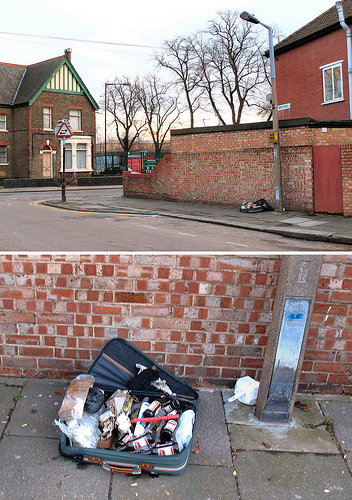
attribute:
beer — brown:
[136, 398, 193, 449]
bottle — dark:
[142, 387, 182, 422]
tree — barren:
[109, 61, 195, 161]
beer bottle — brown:
[145, 392, 171, 414]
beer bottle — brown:
[162, 412, 178, 439]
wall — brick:
[122, 117, 351, 216]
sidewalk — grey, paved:
[101, 158, 349, 271]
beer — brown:
[119, 433, 156, 449]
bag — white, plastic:
[227, 374, 260, 405]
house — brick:
[0, 43, 103, 179]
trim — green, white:
[45, 54, 86, 93]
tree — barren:
[153, 27, 216, 128]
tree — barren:
[197, 11, 272, 126]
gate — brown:
[310, 144, 345, 218]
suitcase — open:
[60, 336, 199, 475]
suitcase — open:
[60, 353, 203, 472]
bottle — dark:
[117, 429, 153, 451]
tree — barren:
[210, 32, 264, 137]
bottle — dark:
[113, 433, 159, 453]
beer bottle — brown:
[112, 435, 179, 459]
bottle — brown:
[122, 426, 155, 453]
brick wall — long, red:
[115, 112, 319, 211]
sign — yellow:
[266, 129, 280, 147]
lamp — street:
[237, 10, 261, 27]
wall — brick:
[118, 141, 350, 217]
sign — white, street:
[53, 121, 72, 139]